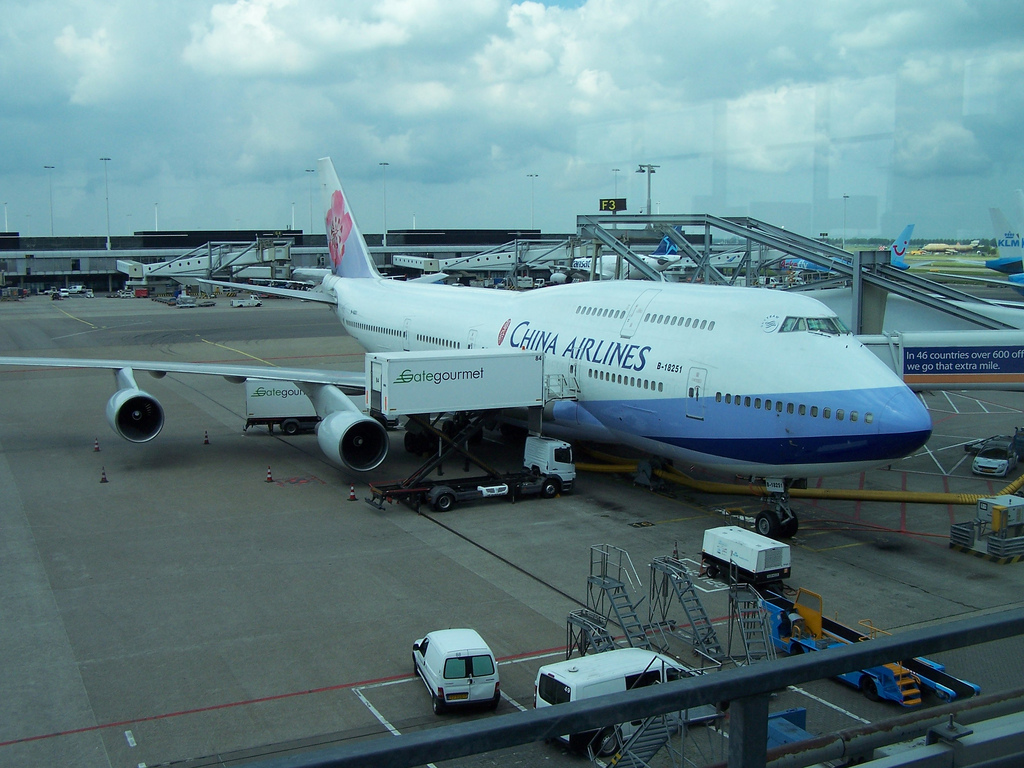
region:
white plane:
[64, 180, 924, 498]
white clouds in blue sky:
[114, 83, 195, 147]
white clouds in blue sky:
[629, 31, 710, 83]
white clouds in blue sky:
[854, 75, 932, 148]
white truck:
[427, 610, 508, 724]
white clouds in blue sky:
[32, 92, 99, 141]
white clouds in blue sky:
[860, 113, 950, 183]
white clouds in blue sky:
[438, 54, 525, 112]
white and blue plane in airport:
[9, 156, 954, 492]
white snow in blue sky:
[740, 0, 823, 80]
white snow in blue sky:
[272, 59, 349, 111]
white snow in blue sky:
[841, 55, 934, 138]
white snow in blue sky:
[720, 46, 777, 113]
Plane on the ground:
[0, 125, 966, 555]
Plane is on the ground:
[1, 138, 1007, 540]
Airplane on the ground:
[0, 130, 1019, 526]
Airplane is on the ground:
[0, 144, 980, 496]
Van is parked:
[399, 617, 513, 726]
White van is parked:
[399, 620, 513, 718]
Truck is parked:
[364, 411, 589, 522]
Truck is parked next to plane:
[348, 419, 589, 522]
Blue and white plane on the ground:
[0, 146, 952, 538]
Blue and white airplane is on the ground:
[0, 137, 958, 552]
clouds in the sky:
[2, 5, 1020, 227]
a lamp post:
[636, 165, 653, 210]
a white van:
[408, 629, 503, 705]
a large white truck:
[361, 433, 570, 498]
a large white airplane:
[0, 152, 928, 532]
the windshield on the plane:
[775, 314, 830, 330]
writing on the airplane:
[484, 320, 656, 372]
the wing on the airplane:
[1, 351, 466, 470]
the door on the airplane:
[677, 364, 700, 413]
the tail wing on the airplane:
[311, 160, 370, 279]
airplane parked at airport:
[4, 104, 1022, 531]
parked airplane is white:
[3, 148, 1021, 537]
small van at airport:
[398, 612, 507, 711]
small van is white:
[402, 618, 511, 724]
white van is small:
[405, 619, 513, 717]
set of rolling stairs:
[537, 532, 733, 695]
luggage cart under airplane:
[690, 517, 792, 590]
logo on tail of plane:
[313, 182, 362, 272]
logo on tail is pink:
[313, 185, 361, 275]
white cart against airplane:
[357, 327, 555, 422]